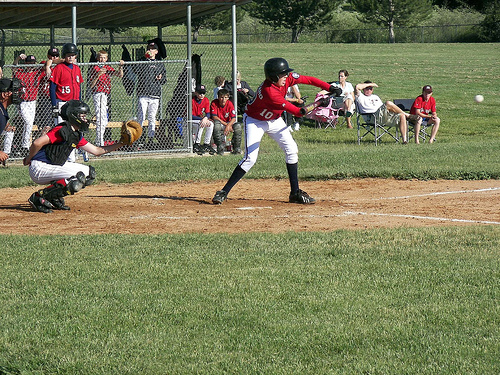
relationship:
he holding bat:
[210, 56, 342, 205] [300, 88, 337, 113]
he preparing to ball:
[210, 56, 342, 205] [472, 89, 487, 104]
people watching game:
[117, 22, 435, 174] [6, 30, 497, 372]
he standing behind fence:
[210, 56, 342, 205] [5, 55, 194, 156]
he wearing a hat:
[210, 56, 342, 205] [262, 57, 292, 84]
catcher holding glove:
[21, 101, 142, 214] [118, 120, 145, 144]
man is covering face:
[365, 80, 403, 137] [353, 81, 375, 88]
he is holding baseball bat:
[210, 56, 342, 205] [295, 87, 349, 113]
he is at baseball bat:
[206, 54, 340, 203] [295, 91, 338, 117]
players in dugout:
[6, 31, 176, 149] [2, 0, 240, 165]